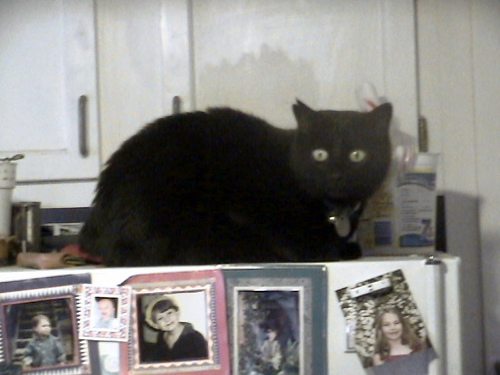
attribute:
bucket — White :
[1, 143, 30, 243]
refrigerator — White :
[404, 148, 484, 370]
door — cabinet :
[10, 5, 110, 185]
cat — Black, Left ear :
[74, 90, 397, 257]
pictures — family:
[3, 262, 462, 368]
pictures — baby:
[78, 284, 133, 343]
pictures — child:
[126, 271, 230, 371]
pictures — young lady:
[334, 271, 431, 370]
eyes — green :
[310, 146, 371, 172]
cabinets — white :
[2, 8, 436, 205]